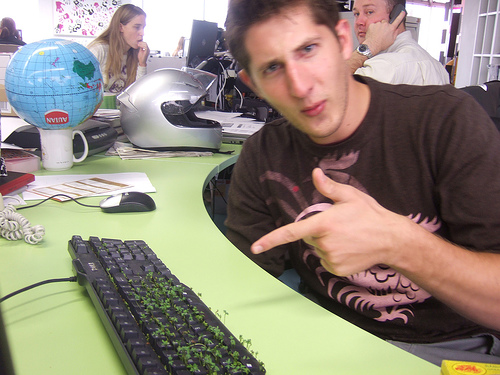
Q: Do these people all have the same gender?
A: No, they are both male and female.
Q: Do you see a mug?
A: Yes, there is a mug.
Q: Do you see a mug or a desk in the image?
A: Yes, there is a mug.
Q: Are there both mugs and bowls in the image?
A: No, there is a mug but no bowls.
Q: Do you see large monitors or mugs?
A: Yes, there is a large mug.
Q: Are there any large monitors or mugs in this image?
A: Yes, there is a large mug.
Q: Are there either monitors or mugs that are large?
A: Yes, the mug is large.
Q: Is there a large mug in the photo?
A: Yes, there is a large mug.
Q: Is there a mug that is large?
A: Yes, there is a mug that is large.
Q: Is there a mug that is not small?
A: Yes, there is a large mug.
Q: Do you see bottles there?
A: No, there are no bottles.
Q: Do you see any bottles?
A: No, there are no bottles.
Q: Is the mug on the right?
A: No, the mug is on the left of the image.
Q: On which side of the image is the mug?
A: The mug is on the left of the image.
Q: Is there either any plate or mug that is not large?
A: No, there is a mug but it is large.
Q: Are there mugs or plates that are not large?
A: No, there is a mug but it is large.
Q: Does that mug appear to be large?
A: Yes, the mug is large.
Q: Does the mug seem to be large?
A: Yes, the mug is large.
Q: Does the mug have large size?
A: Yes, the mug is large.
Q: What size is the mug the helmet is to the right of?
A: The mug is large.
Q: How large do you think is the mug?
A: The mug is large.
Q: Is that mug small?
A: No, the mug is large.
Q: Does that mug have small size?
A: No, the mug is large.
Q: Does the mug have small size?
A: No, the mug is large.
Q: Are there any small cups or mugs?
A: No, there is a mug but it is large.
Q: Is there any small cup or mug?
A: No, there is a mug but it is large.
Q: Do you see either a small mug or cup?
A: No, there is a mug but it is large.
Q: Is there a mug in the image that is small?
A: No, there is a mug but it is large.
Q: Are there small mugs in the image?
A: No, there is a mug but it is large.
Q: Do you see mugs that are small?
A: No, there is a mug but it is large.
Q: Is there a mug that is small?
A: No, there is a mug but it is large.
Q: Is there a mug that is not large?
A: No, there is a mug but it is large.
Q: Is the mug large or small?
A: The mug is large.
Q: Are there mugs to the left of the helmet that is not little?
A: Yes, there is a mug to the left of the helmet.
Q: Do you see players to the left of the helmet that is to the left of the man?
A: No, there is a mug to the left of the helmet.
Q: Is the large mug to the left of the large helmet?
A: Yes, the mug is to the left of the helmet.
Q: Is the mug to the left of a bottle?
A: No, the mug is to the left of the helmet.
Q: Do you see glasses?
A: No, there are no glasses.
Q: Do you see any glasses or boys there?
A: No, there are no glasses or boys.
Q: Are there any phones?
A: Yes, there is a phone.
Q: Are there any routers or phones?
A: Yes, there is a phone.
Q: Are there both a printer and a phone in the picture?
A: No, there is a phone but no printers.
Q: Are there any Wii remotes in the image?
A: No, there are no Wii remotes.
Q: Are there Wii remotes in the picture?
A: No, there are no Wii remotes.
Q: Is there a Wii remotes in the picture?
A: No, there are no Wii controllers.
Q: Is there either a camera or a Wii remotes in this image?
A: No, there are no Wii controllers or cameras.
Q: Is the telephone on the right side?
A: Yes, the telephone is on the right of the image.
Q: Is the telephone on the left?
A: No, the telephone is on the right of the image.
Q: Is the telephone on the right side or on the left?
A: The telephone is on the right of the image.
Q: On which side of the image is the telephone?
A: The telephone is on the right of the image.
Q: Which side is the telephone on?
A: The telephone is on the right of the image.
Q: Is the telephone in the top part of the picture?
A: Yes, the telephone is in the top of the image.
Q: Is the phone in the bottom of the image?
A: No, the phone is in the top of the image.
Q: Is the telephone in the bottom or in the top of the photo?
A: The telephone is in the top of the image.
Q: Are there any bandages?
A: No, there are no bandages.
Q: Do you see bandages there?
A: No, there are no bandages.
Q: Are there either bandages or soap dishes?
A: No, there are no bandages or soap dishes.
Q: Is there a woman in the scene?
A: Yes, there is a woman.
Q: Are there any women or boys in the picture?
A: Yes, there is a woman.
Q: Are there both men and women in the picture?
A: Yes, there are both a woman and a man.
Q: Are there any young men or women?
A: Yes, there is a young woman.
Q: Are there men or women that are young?
A: Yes, the woman is young.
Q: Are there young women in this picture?
A: Yes, there is a young woman.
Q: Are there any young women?
A: Yes, there is a young woman.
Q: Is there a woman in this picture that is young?
A: Yes, there is a woman that is young.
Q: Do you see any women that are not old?
A: Yes, there is an young woman.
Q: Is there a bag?
A: No, there are no bags.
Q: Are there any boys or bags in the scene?
A: No, there are no bags or boys.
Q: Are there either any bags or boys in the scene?
A: No, there are no bags or boys.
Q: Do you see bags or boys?
A: No, there are no bags or boys.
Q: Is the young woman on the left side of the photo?
A: Yes, the woman is on the left of the image.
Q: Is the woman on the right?
A: No, the woman is on the left of the image.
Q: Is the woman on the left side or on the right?
A: The woman is on the left of the image.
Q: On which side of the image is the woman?
A: The woman is on the left of the image.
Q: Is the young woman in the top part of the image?
A: Yes, the woman is in the top of the image.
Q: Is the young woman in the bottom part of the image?
A: No, the woman is in the top of the image.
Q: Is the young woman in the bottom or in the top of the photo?
A: The woman is in the top of the image.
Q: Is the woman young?
A: Yes, the woman is young.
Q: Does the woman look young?
A: Yes, the woman is young.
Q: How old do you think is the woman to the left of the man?
A: The woman is young.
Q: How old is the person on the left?
A: The woman is young.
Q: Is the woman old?
A: No, the woman is young.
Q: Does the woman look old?
A: No, the woman is young.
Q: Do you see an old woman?
A: No, there is a woman but she is young.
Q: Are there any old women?
A: No, there is a woman but she is young.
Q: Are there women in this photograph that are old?
A: No, there is a woman but she is young.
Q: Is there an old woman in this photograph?
A: No, there is a woman but she is young.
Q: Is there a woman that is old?
A: No, there is a woman but she is young.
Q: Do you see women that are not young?
A: No, there is a woman but she is young.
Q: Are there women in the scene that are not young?
A: No, there is a woman but she is young.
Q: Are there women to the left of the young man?
A: Yes, there is a woman to the left of the man.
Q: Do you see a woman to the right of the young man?
A: No, the woman is to the left of the man.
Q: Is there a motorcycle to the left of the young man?
A: No, there is a woman to the left of the man.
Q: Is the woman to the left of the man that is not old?
A: Yes, the woman is to the left of the man.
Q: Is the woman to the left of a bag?
A: No, the woman is to the left of the man.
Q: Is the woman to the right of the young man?
A: No, the woman is to the left of the man.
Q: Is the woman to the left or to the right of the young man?
A: The woman is to the left of the man.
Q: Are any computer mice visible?
A: Yes, there is a computer mouse.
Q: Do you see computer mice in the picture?
A: Yes, there is a computer mouse.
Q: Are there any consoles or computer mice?
A: Yes, there is a computer mouse.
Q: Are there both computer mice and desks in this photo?
A: Yes, there are both a computer mouse and a desk.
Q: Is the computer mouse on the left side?
A: Yes, the computer mouse is on the left of the image.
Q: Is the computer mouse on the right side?
A: No, the computer mouse is on the left of the image.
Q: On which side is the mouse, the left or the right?
A: The mouse is on the left of the image.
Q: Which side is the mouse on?
A: The mouse is on the left of the image.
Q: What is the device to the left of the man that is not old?
A: The device is a computer mouse.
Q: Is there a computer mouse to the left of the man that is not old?
A: Yes, there is a computer mouse to the left of the man.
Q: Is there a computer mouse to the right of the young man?
A: No, the computer mouse is to the left of the man.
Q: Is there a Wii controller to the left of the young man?
A: No, there is a computer mouse to the left of the man.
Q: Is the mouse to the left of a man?
A: Yes, the mouse is to the left of a man.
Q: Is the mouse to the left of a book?
A: No, the mouse is to the left of a man.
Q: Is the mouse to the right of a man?
A: No, the mouse is to the left of a man.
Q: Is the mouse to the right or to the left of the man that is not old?
A: The mouse is to the left of the man.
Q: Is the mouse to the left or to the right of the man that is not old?
A: The mouse is to the left of the man.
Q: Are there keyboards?
A: Yes, there is a keyboard.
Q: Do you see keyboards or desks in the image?
A: Yes, there is a keyboard.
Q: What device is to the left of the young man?
A: The device is a keyboard.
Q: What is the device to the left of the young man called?
A: The device is a keyboard.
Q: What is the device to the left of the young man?
A: The device is a keyboard.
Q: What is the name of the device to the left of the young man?
A: The device is a keyboard.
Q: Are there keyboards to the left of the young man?
A: Yes, there is a keyboard to the left of the man.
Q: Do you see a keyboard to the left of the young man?
A: Yes, there is a keyboard to the left of the man.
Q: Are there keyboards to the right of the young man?
A: No, the keyboard is to the left of the man.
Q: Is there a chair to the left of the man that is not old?
A: No, there is a keyboard to the left of the man.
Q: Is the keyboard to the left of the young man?
A: Yes, the keyboard is to the left of the man.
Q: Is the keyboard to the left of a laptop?
A: No, the keyboard is to the left of the man.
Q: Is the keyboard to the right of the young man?
A: No, the keyboard is to the left of the man.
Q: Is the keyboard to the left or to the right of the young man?
A: The keyboard is to the left of the man.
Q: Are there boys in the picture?
A: No, there are no boys.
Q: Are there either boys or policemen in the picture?
A: No, there are no boys or policemen.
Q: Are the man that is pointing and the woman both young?
A: Yes, both the man and the woman are young.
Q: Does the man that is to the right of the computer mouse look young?
A: Yes, the man is young.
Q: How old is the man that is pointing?
A: The man is young.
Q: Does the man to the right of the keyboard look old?
A: No, the man is young.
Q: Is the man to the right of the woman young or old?
A: The man is young.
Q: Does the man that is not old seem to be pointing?
A: Yes, the man is pointing.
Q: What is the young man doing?
A: The man is pointing.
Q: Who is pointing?
A: The man is pointing.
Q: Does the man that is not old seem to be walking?
A: No, the man is pointing.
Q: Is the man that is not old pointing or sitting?
A: The man is pointing.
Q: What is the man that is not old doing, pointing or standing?
A: The man is pointing.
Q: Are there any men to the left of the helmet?
A: No, the man is to the right of the helmet.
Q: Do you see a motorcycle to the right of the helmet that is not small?
A: No, there is a man to the right of the helmet.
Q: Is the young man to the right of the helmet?
A: Yes, the man is to the right of the helmet.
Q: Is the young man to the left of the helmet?
A: No, the man is to the right of the helmet.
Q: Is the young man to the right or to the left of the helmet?
A: The man is to the right of the helmet.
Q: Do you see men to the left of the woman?
A: No, the man is to the right of the woman.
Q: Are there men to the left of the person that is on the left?
A: No, the man is to the right of the woman.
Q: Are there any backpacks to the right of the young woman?
A: No, there is a man to the right of the woman.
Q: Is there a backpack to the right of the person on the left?
A: No, there is a man to the right of the woman.